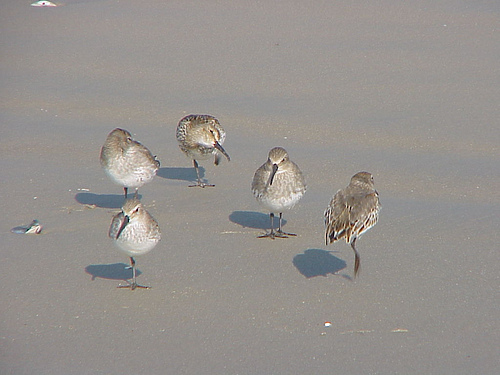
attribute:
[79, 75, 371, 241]
birds — standing, taking, breeding, grouped, attempting, hiding, scratching, grey, white, here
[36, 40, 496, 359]
ground — five, sandy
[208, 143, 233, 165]
beak — gray, black, here, long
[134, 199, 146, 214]
eye — small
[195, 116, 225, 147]
head — bent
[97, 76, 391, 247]
sandpipers — spotted, cynical, gang, itchy, crabby, turned, cranky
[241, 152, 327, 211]
bird — grey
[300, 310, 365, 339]
stone — white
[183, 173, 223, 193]
leg — here